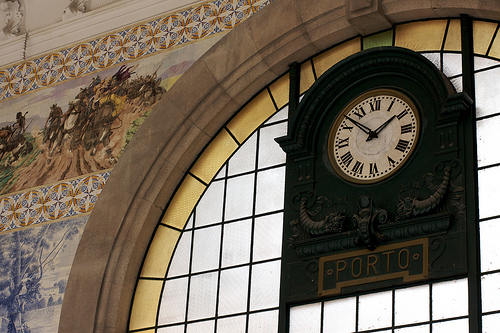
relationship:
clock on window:
[319, 83, 429, 187] [66, 1, 500, 332]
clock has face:
[319, 83, 429, 187] [350, 114, 404, 161]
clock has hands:
[319, 83, 429, 187] [346, 116, 399, 142]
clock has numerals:
[319, 83, 429, 187] [367, 100, 383, 113]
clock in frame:
[319, 83, 429, 187] [274, 43, 479, 305]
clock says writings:
[319, 83, 429, 187] [335, 248, 410, 281]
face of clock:
[350, 114, 404, 161] [319, 83, 429, 187]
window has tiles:
[66, 1, 500, 332] [215, 164, 285, 267]